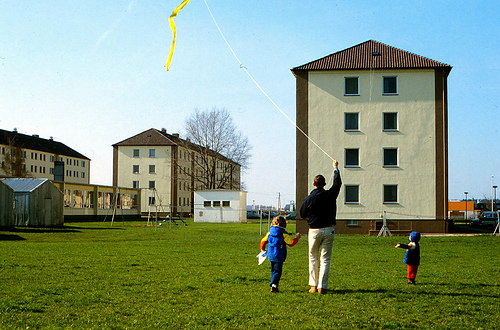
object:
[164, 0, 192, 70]
kite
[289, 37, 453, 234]
building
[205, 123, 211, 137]
branch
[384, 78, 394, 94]
windows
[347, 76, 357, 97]
windows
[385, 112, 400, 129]
windows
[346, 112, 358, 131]
windows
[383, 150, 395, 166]
windows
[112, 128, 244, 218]
building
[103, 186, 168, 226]
swing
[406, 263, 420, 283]
pants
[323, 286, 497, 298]
shadow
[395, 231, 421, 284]
boy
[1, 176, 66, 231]
shed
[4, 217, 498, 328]
grass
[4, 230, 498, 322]
area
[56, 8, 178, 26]
clouds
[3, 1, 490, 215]
sky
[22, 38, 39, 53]
clouds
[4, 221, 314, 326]
yard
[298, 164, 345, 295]
man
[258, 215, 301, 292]
child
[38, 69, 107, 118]
clouds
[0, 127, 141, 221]
building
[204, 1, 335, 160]
string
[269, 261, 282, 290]
pants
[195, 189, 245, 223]
shack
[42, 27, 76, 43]
clouds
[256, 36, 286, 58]
clouds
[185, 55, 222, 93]
clouds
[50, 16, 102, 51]
clouds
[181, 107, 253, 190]
tree